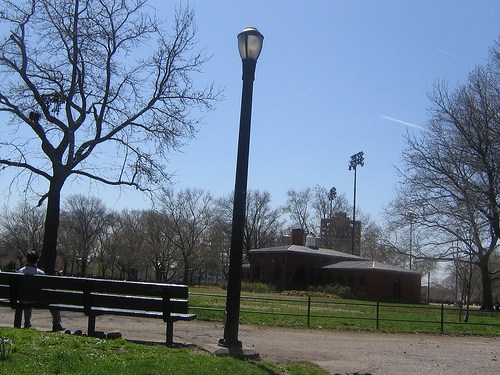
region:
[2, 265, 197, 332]
wooden bench in a park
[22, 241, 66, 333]
one person sitting on bench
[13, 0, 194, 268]
tall tree with no leaves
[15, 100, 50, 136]
birds nest in the tree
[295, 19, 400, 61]
clear light blue sky with no clouds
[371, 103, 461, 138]
white airplane lines in the sky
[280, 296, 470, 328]
small wooden fence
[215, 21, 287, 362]
old fashioned decorative street light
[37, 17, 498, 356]
photograph taken in a park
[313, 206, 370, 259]
tall buildings in the background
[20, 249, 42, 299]
A person sitting on a bench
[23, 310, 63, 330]
Legs on the ground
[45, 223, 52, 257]
A tree trunk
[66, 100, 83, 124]
Tree branches and the sky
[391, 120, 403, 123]
White foam in the sky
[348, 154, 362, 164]
Flood lights high up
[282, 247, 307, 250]
The roof a low building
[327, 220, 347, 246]
An apartment building behind the trees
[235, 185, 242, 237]
A thick lamp post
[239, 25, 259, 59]
A lamp on a pole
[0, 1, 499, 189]
blue of daytime sky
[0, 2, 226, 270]
tree with no leaves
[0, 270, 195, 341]
back of wood bench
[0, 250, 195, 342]
one person on bench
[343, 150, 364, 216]
multiple lights on pole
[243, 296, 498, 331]
fence in front of grass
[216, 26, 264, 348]
street light on pole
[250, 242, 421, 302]
two sections of building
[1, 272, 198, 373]
green grass behind bench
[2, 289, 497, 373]
walkway surface in park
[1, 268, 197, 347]
A very long dark colored bench a man is sitting on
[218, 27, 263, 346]
A black light pole slanted to the right.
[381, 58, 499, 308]
A leafless tree to the far right of a light pole.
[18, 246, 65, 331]
A man sitting on a long bench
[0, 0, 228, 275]
A leafless tree directly in front of a man sitting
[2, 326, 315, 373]
Green grassy area behind a bench.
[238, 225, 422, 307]
A brick building with a chimney directly across through the grass.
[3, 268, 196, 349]
A long bench a man is sitting on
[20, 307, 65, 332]
Legs and feet of a man on a bench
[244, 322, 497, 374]
A grey road to the right of a light pole.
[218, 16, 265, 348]
the tall and black light post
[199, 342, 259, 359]
the cement block under the light post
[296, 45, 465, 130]
the white markings in the blue sky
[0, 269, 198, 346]
the bench near the walkway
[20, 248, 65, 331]
the person on the bench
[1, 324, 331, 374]
the grass behind the bench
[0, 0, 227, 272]
the tree right in front of the bench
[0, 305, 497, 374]
the walkway in front of the bench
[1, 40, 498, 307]
the trees near the building structure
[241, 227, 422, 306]
the building structure on the grass